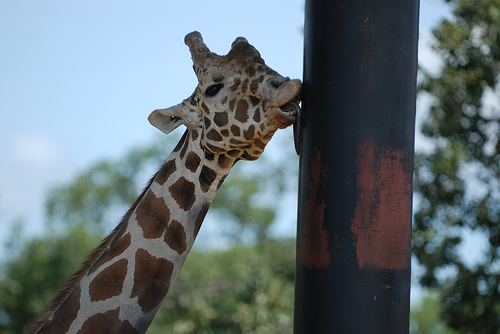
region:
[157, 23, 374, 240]
giraffe licking the post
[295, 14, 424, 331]
the post is black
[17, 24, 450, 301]
this is a giraffe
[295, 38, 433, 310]
this is a street pole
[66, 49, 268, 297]
the giraffe is licking the pole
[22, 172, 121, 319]
the giraffe is spotted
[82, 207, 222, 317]
the giraffe is tan and brown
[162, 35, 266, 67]
the giraffe has a horn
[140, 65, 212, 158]
the giraffes ears are white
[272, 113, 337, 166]
the giraffes tongue is black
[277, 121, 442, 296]
the pole is painted partially red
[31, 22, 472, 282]
the background is trees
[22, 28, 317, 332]
Brown and white giraffe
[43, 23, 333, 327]
Giraffe licking the pole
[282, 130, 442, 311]
Brown spots on black pole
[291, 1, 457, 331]
Tall and thick black pole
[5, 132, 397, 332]
Trees in the distance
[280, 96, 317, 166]
Black giraffe tounge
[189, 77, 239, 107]
Black giraffe eye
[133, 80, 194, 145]
White giraffe ear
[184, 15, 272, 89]
Two horns on giraffes head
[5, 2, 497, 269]
Clear blue sky in the background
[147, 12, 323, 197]
giraffe licking a pole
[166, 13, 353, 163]
giraffe's tongue on pole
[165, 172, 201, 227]
brown spot of giraffe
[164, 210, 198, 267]
brown spot of giraffe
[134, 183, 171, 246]
brown spot of giraffe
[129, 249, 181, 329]
brown spot of giraffe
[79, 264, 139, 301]
brown spot of giraffe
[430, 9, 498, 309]
tall green leafy tree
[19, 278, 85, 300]
hair on spotted giraffe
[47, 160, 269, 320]
neck of spotted giraffe